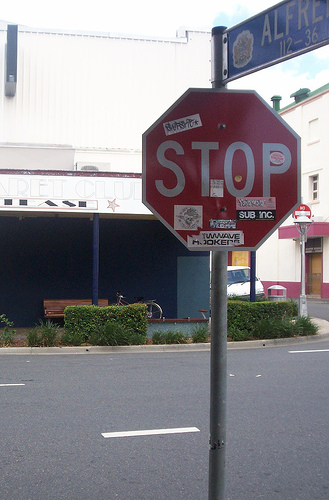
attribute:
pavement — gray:
[57, 361, 317, 413]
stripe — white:
[94, 412, 220, 454]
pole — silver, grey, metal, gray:
[195, 259, 244, 499]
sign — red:
[148, 90, 328, 230]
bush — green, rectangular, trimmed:
[58, 290, 168, 338]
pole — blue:
[88, 217, 113, 302]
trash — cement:
[267, 281, 287, 302]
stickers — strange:
[170, 121, 288, 228]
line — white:
[111, 411, 204, 444]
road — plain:
[11, 358, 326, 496]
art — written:
[206, 184, 235, 219]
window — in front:
[230, 268, 260, 280]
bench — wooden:
[33, 292, 111, 303]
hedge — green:
[231, 300, 324, 336]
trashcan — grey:
[265, 282, 299, 299]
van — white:
[226, 268, 266, 299]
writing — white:
[237, 210, 262, 221]